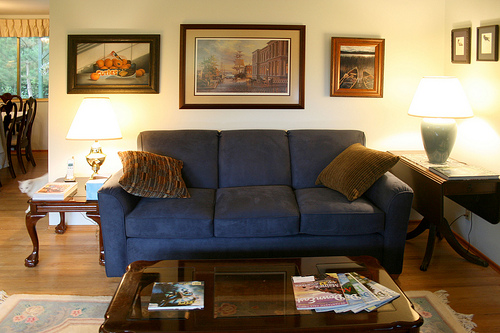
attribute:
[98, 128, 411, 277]
couch — dark blue, in center, blue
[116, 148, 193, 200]
pillow — large, brown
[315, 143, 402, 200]
pillow — large, on the left side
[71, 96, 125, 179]
table lamp — lit, on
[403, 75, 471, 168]
table lamp — lit, plugged in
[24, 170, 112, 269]
end table — wooden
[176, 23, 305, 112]
art print — framed, wooden framed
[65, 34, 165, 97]
art print — framed, picture of fruit, oranges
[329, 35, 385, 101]
art print — framed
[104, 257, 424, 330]
center table — glass topped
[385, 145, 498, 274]
side table — long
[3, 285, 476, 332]
rug — fringed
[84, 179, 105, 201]
box — blue, small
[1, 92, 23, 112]
chair — wooden, in background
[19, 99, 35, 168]
chair — in background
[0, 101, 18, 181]
chair — in background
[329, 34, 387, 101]
frame — wooden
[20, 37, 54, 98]
tree — in background